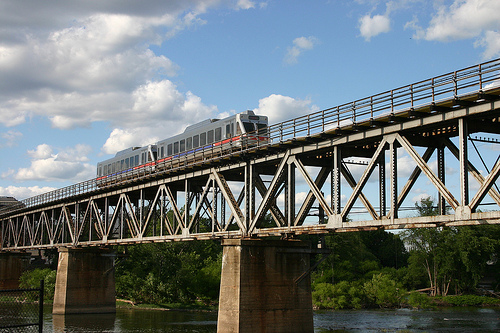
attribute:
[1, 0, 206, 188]
clouds — white, gray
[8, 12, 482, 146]
sky — cloudy, blue, white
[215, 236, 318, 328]
pillar — cement, supporting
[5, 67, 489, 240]
bridge — metal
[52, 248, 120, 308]
pillar — concrete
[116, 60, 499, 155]
rail — metal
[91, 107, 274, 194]
train — traveling, gray, short, silver, red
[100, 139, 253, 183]
stripes — orange, blue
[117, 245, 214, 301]
trees — green, leafy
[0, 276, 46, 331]
fence — mesh, black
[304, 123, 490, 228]
beam — steel